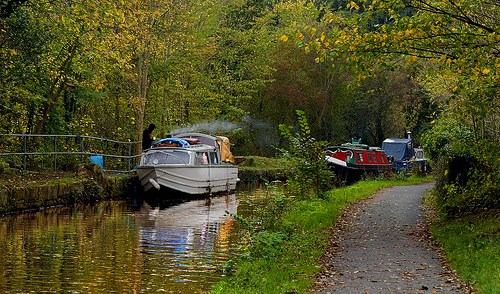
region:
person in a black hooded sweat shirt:
[137, 120, 158, 152]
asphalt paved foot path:
[310, 178, 460, 292]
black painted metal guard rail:
[2, 123, 144, 186]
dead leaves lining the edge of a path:
[301, 186, 387, 290]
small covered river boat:
[125, 120, 246, 197]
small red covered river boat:
[310, 135, 390, 183]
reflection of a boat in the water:
[131, 184, 246, 261]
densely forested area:
[4, 5, 499, 205]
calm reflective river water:
[6, 165, 282, 292]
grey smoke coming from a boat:
[165, 110, 271, 143]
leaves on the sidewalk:
[351, 221, 418, 285]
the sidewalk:
[375, 188, 413, 214]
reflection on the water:
[150, 203, 211, 238]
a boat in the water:
[142, 170, 236, 200]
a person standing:
[142, 120, 159, 147]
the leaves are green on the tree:
[221, 48, 273, 92]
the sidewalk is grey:
[382, 187, 409, 212]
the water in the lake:
[42, 235, 172, 285]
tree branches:
[43, 81, 70, 99]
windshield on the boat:
[142, 148, 177, 163]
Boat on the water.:
[118, 88, 323, 243]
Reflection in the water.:
[126, 146, 263, 280]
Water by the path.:
[131, 179, 301, 269]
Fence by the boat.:
[34, 94, 137, 200]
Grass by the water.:
[242, 139, 423, 273]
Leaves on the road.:
[311, 189, 391, 251]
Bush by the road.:
[269, 95, 375, 234]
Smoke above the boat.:
[148, 89, 287, 136]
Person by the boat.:
[133, 98, 175, 165]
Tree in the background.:
[39, 9, 284, 167]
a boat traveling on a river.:
[129, 111, 257, 210]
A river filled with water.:
[0, 151, 322, 291]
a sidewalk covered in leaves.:
[315, 168, 447, 292]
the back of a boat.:
[207, 125, 243, 165]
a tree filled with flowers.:
[276, 0, 498, 228]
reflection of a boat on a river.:
[129, 185, 259, 267]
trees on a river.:
[259, 110, 350, 212]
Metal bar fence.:
[0, 134, 147, 171]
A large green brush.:
[253, 116, 335, 194]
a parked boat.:
[312, 110, 429, 179]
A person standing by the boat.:
[141, 114, 166, 160]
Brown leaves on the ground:
[314, 213, 439, 284]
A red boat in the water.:
[321, 128, 407, 174]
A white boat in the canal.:
[126, 118, 261, 197]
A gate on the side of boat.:
[13, 119, 154, 171]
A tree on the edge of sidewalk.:
[272, 113, 336, 204]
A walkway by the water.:
[352, 166, 465, 292]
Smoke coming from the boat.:
[166, 116, 271, 136]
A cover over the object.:
[383, 132, 417, 163]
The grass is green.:
[405, 196, 489, 281]